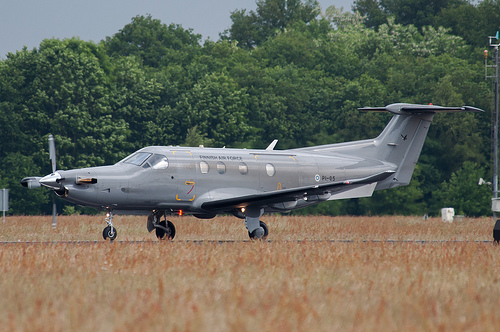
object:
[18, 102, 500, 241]
plane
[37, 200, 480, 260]
runway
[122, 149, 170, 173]
windows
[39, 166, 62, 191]
propeller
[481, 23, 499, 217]
tower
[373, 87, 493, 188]
tail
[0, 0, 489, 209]
trees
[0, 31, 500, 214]
background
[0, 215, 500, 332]
grass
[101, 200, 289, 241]
landing gear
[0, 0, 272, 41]
skies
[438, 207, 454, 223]
bucket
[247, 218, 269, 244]
wheel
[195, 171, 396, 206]
wing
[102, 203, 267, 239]
wheels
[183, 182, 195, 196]
7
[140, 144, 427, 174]
back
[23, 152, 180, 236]
front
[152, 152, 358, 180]
side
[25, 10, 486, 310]
scene